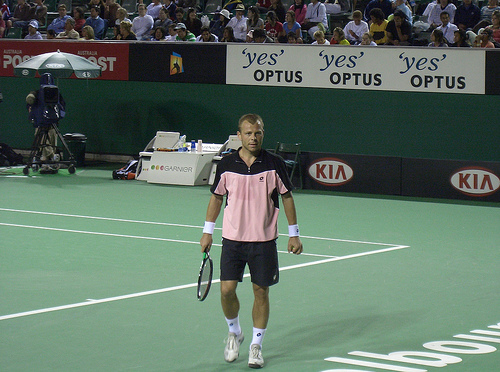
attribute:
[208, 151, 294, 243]
shirt — PINK, BLACK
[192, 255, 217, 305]
tennis racket — BLACK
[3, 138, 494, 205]
kia sign — RED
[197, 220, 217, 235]
wrist band — WHITE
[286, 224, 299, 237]
wrist band — WHITE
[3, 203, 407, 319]
markings — WHITE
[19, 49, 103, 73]
umbrella — GREEN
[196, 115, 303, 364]
man — light skinned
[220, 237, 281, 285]
shorts — black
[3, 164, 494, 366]
playing ground — blue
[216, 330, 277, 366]
shoes — white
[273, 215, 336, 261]
wristband — white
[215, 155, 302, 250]
shirt — light, dark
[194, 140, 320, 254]
shirt — short sleeved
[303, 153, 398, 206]
advertisment — red, white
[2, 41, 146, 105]
umbrella — white, green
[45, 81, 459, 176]
barrier — dark green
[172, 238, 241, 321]
racket — black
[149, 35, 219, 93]
sign — small, yellow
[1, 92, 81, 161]
person — crouched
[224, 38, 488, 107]
banner — white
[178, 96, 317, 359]
player — tennis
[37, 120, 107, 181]
garbage can — green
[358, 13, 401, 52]
shirt — yellow, black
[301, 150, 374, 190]
sign — white, red